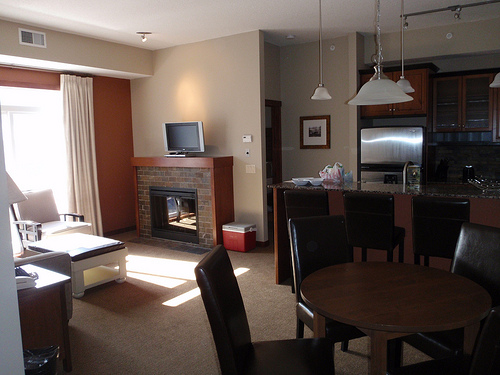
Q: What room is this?
A: It is a kitchen.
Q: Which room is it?
A: It is a kitchen.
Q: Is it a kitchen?
A: Yes, it is a kitchen.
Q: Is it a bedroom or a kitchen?
A: It is a kitchen.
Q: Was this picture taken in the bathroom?
A: No, the picture was taken in the kitchen.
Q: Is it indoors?
A: Yes, it is indoors.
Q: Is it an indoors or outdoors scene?
A: It is indoors.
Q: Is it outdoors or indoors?
A: It is indoors.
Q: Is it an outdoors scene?
A: No, it is indoors.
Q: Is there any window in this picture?
A: Yes, there is a window.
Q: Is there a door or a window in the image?
A: Yes, there is a window.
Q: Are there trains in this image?
A: No, there are no trains.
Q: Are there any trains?
A: No, there are no trains.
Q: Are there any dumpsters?
A: No, there are no dumpsters.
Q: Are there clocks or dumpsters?
A: No, there are no dumpsters or clocks.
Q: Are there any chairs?
A: Yes, there is a chair.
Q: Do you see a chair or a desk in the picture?
A: Yes, there is a chair.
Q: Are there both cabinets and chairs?
A: Yes, there are both a chair and a cabinet.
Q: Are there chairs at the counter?
A: Yes, there is a chair at the counter.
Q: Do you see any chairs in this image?
A: Yes, there is a chair.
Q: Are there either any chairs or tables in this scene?
A: Yes, there is a chair.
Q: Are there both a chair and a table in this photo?
A: Yes, there are both a chair and a table.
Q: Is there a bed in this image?
A: No, there are no beds.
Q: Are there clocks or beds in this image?
A: No, there are no beds or clocks.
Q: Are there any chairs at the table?
A: Yes, there is a chair at the table.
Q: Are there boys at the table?
A: No, there is a chair at the table.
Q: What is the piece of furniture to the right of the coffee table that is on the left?
A: The piece of furniture is a chair.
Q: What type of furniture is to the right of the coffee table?
A: The piece of furniture is a chair.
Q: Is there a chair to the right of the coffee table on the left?
A: Yes, there is a chair to the right of the coffee table.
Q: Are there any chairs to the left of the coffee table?
A: No, the chair is to the right of the coffee table.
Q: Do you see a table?
A: Yes, there is a table.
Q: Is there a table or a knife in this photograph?
A: Yes, there is a table.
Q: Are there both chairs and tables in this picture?
A: Yes, there are both a table and a chair.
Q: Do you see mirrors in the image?
A: No, there are no mirrors.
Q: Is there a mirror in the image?
A: No, there are no mirrors.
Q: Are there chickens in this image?
A: No, there are no chickens.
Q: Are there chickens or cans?
A: No, there are no chickens or cans.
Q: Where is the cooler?
A: The cooler is on the floor.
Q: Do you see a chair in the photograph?
A: Yes, there is a chair.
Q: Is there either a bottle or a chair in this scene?
A: Yes, there is a chair.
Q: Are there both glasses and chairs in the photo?
A: Yes, there are both a chair and glasses.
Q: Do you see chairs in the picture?
A: Yes, there is a chair.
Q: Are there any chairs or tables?
A: Yes, there is a chair.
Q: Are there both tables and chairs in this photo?
A: Yes, there are both a chair and a table.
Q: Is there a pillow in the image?
A: No, there are no pillows.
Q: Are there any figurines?
A: No, there are no figurines.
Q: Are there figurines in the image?
A: No, there are no figurines.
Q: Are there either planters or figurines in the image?
A: No, there are no figurines or planters.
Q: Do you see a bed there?
A: No, there are no beds.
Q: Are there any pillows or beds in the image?
A: No, there are no beds or pillows.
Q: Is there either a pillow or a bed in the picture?
A: No, there are no beds or pillows.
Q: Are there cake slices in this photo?
A: No, there are no cake slices.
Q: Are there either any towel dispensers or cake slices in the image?
A: No, there are no cake slices or towel dispensers.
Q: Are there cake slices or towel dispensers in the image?
A: No, there are no cake slices or towel dispensers.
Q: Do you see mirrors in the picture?
A: No, there are no mirrors.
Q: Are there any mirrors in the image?
A: No, there are no mirrors.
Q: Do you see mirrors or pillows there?
A: No, there are no mirrors or pillows.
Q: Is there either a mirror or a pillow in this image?
A: No, there are no mirrors or pillows.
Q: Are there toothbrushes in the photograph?
A: No, there are no toothbrushes.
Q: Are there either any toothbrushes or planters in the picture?
A: No, there are no toothbrushes or planters.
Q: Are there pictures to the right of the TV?
A: Yes, there is a picture to the right of the TV.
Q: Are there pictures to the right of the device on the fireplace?
A: Yes, there is a picture to the right of the TV.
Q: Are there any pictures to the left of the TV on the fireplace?
A: No, the picture is to the right of the TV.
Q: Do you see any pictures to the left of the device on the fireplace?
A: No, the picture is to the right of the TV.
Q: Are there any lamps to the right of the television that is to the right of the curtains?
A: No, there is a picture to the right of the television.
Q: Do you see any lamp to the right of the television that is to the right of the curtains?
A: No, there is a picture to the right of the television.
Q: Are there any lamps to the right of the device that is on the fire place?
A: No, there is a picture to the right of the television.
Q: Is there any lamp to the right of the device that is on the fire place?
A: No, there is a picture to the right of the television.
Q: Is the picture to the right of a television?
A: Yes, the picture is to the right of a television.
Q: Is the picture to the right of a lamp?
A: No, the picture is to the right of a television.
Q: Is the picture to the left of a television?
A: No, the picture is to the right of a television.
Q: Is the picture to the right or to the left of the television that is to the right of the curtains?
A: The picture is to the right of the television.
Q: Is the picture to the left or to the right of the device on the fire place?
A: The picture is to the right of the television.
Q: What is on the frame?
A: The picture is on the frame.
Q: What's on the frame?
A: The picture is on the frame.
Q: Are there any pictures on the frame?
A: Yes, there is a picture on the frame.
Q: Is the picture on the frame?
A: Yes, the picture is on the frame.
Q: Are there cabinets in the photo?
A: Yes, there is a cabinet.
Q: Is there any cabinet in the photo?
A: Yes, there is a cabinet.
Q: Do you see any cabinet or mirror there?
A: Yes, there is a cabinet.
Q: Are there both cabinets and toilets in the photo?
A: No, there is a cabinet but no toilets.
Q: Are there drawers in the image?
A: No, there are no drawers.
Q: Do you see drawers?
A: No, there are no drawers.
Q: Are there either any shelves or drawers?
A: No, there are no drawers or shelves.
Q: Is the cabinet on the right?
A: Yes, the cabinet is on the right of the image.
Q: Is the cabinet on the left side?
A: No, the cabinet is on the right of the image.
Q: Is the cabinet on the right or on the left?
A: The cabinet is on the right of the image.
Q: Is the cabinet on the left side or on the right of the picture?
A: The cabinet is on the right of the image.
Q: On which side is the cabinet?
A: The cabinet is on the right of the image.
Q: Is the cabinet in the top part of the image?
A: Yes, the cabinet is in the top of the image.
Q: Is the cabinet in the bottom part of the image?
A: No, the cabinet is in the top of the image.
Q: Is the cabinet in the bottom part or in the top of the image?
A: The cabinet is in the top of the image.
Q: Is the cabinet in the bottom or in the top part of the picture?
A: The cabinet is in the top of the image.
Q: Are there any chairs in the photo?
A: Yes, there is a chair.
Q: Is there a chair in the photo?
A: Yes, there is a chair.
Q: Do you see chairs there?
A: Yes, there is a chair.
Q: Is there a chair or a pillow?
A: Yes, there is a chair.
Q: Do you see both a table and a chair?
A: Yes, there are both a chair and a table.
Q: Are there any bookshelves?
A: No, there are no bookshelves.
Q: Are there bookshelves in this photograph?
A: No, there are no bookshelves.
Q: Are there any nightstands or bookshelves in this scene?
A: No, there are no bookshelves or nightstands.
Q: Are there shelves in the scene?
A: No, there are no shelves.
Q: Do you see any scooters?
A: No, there are no scooters.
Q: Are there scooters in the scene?
A: No, there are no scooters.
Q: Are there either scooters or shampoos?
A: No, there are no scooters or shampoos.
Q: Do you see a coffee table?
A: Yes, there is a coffee table.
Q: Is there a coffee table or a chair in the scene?
A: Yes, there is a coffee table.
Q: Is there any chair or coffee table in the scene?
A: Yes, there is a coffee table.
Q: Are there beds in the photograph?
A: No, there are no beds.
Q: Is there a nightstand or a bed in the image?
A: No, there are no beds or nightstands.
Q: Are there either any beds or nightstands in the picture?
A: No, there are no beds or nightstands.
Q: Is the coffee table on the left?
A: Yes, the coffee table is on the left of the image.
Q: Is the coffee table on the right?
A: No, the coffee table is on the left of the image.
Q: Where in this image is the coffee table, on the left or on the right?
A: The coffee table is on the left of the image.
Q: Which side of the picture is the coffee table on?
A: The coffee table is on the left of the image.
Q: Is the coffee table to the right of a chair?
A: No, the coffee table is to the left of a chair.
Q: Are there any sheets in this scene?
A: No, there are no sheets.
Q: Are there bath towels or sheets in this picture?
A: No, there are no sheets or bath towels.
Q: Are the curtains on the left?
A: Yes, the curtains are on the left of the image.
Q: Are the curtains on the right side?
A: No, the curtains are on the left of the image.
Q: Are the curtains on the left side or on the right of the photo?
A: The curtains are on the left of the image.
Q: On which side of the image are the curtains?
A: The curtains are on the left of the image.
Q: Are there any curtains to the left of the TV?
A: Yes, there are curtains to the left of the TV.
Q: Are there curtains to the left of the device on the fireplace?
A: Yes, there are curtains to the left of the TV.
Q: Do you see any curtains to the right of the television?
A: No, the curtains are to the left of the television.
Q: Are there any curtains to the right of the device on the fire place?
A: No, the curtains are to the left of the television.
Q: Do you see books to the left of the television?
A: No, there are curtains to the left of the television.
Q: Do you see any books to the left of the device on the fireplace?
A: No, there are curtains to the left of the television.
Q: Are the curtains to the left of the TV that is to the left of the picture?
A: Yes, the curtains are to the left of the television.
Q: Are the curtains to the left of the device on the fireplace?
A: Yes, the curtains are to the left of the television.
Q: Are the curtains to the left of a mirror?
A: No, the curtains are to the left of the television.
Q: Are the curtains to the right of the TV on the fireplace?
A: No, the curtains are to the left of the television.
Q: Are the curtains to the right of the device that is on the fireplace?
A: No, the curtains are to the left of the television.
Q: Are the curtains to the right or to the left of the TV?
A: The curtains are to the left of the TV.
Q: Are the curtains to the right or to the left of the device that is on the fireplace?
A: The curtains are to the left of the TV.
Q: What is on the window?
A: The curtains are on the window.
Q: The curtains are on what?
A: The curtains are on the window.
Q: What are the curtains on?
A: The curtains are on the window.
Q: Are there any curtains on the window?
A: Yes, there are curtains on the window.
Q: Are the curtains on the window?
A: Yes, the curtains are on the window.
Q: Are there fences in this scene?
A: No, there are no fences.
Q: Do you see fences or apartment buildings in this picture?
A: No, there are no fences or apartment buildings.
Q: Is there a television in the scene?
A: Yes, there is a television.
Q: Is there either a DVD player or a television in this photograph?
A: Yes, there is a television.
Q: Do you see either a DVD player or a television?
A: Yes, there is a television.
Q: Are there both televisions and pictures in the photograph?
A: Yes, there are both a television and a picture.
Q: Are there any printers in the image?
A: No, there are no printers.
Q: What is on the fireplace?
A: The TV is on the fireplace.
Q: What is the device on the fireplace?
A: The device is a television.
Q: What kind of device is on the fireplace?
A: The device is a television.